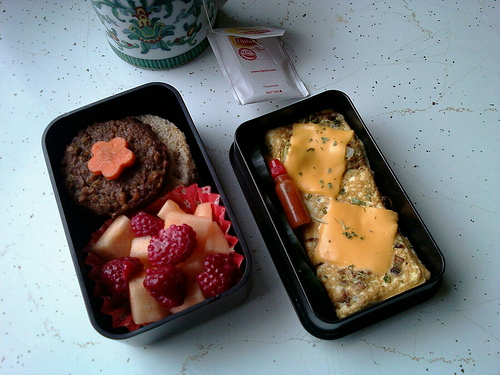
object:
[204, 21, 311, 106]
tea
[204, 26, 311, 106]
bag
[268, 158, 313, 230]
bottle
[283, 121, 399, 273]
cheese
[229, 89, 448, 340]
pan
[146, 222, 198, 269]
berries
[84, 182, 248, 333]
cupcake tin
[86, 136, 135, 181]
carrot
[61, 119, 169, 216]
hamburger